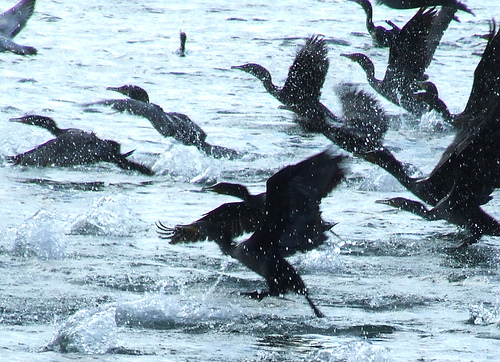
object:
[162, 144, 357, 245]
bird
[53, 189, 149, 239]
droplets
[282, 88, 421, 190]
duck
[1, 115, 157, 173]
bird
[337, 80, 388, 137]
wings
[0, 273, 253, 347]
water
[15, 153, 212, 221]
water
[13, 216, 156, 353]
river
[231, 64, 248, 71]
beak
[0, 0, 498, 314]
flock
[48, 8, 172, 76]
air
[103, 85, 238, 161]
bird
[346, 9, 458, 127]
bird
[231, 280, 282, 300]
foot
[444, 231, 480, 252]
foot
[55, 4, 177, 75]
water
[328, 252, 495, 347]
water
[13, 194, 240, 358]
water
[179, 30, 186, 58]
bird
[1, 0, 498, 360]
scene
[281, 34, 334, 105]
wing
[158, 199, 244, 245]
wing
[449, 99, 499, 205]
wing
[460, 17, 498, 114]
wing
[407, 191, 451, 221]
neck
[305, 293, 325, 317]
feather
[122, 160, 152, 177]
feather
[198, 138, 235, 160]
feather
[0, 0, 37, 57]
bird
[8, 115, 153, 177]
bird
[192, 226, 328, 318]
bird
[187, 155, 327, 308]
bird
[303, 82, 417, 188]
bird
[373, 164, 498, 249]
bird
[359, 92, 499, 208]
bird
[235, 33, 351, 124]
bird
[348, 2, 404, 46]
bird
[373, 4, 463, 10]
bird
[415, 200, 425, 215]
droplets